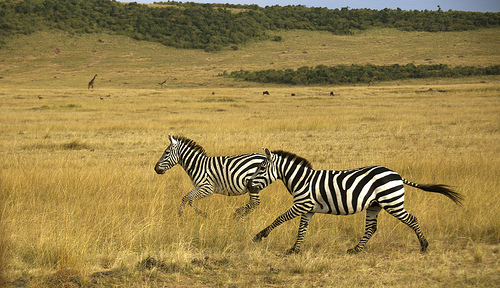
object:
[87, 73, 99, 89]
giraffe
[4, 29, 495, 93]
background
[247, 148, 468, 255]
zebra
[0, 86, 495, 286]
grass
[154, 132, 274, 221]
zebras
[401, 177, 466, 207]
tail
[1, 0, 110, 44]
bushes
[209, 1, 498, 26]
sky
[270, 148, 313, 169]
mane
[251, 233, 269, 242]
hoof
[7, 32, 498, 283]
field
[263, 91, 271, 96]
animals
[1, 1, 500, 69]
hill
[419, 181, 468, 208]
hair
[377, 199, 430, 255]
legs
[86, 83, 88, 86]
tail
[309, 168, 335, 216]
stripes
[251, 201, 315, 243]
leg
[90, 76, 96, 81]
neck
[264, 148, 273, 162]
ears